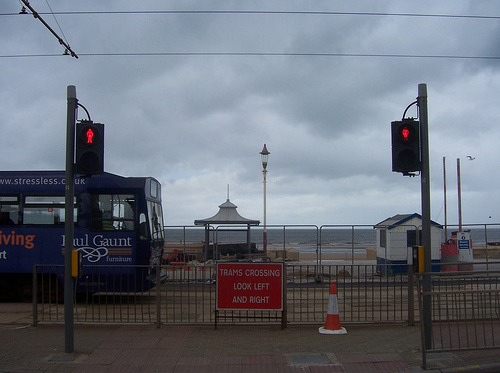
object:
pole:
[414, 81, 440, 357]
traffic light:
[389, 108, 424, 179]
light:
[247, 140, 272, 176]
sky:
[205, 79, 301, 112]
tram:
[0, 172, 163, 291]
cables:
[65, 1, 499, 30]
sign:
[394, 124, 418, 141]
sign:
[218, 260, 280, 315]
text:
[217, 265, 283, 281]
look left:
[223, 280, 274, 293]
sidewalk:
[107, 336, 275, 372]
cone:
[328, 281, 338, 293]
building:
[373, 211, 446, 277]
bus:
[0, 164, 168, 301]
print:
[77, 233, 133, 248]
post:
[62, 103, 77, 341]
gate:
[2, 262, 64, 331]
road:
[87, 283, 208, 326]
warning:
[459, 236, 469, 252]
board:
[459, 247, 474, 263]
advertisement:
[7, 173, 68, 190]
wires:
[185, 5, 249, 20]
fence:
[350, 270, 409, 300]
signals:
[72, 111, 108, 180]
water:
[290, 229, 313, 246]